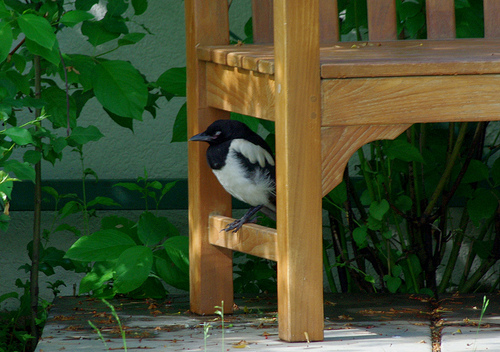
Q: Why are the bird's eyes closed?
A: It is resting.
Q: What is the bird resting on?
A: A wooden bench.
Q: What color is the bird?
A: Black and white.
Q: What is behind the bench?
A: Greenery.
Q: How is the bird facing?
A: To the left.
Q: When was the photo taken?
A: Daytime.